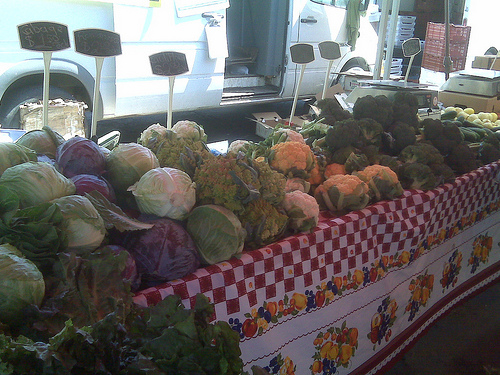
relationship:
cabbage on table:
[53, 129, 198, 281] [15, 84, 499, 366]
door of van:
[98, 2, 231, 103] [2, 7, 393, 109]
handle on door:
[196, 12, 221, 33] [98, 2, 231, 103]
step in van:
[218, 67, 281, 89] [0, 0, 385, 175]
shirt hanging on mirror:
[346, 0, 372, 52] [358, 0, 370, 14]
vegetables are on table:
[21, 141, 443, 273] [26, 107, 498, 369]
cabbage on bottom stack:
[134, 216, 196, 283] [32, 120, 177, 270]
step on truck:
[220, 72, 265, 90] [11, 9, 387, 109]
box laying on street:
[249, 106, 327, 148] [359, 294, 491, 374]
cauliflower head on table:
[309, 172, 373, 216] [71, 161, 496, 373]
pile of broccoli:
[323, 90, 480, 204] [324, 87, 475, 190]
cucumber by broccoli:
[460, 127, 480, 140] [426, 115, 464, 155]